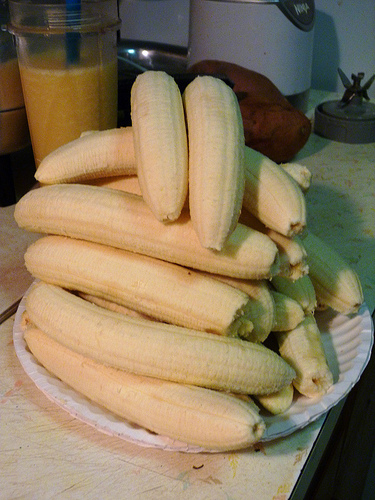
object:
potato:
[188, 56, 310, 173]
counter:
[0, 83, 375, 500]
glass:
[13, 0, 122, 188]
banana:
[33, 124, 308, 240]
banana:
[10, 182, 281, 282]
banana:
[16, 237, 256, 337]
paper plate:
[330, 328, 348, 357]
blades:
[337, 66, 353, 90]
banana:
[126, 70, 190, 226]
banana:
[243, 143, 307, 237]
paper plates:
[11, 269, 375, 458]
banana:
[183, 72, 249, 254]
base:
[186, 0, 316, 157]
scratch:
[119, 460, 230, 494]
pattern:
[337, 156, 361, 182]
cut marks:
[0, 387, 83, 500]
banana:
[23, 275, 298, 399]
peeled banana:
[11, 68, 364, 453]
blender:
[187, 0, 315, 115]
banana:
[302, 231, 362, 315]